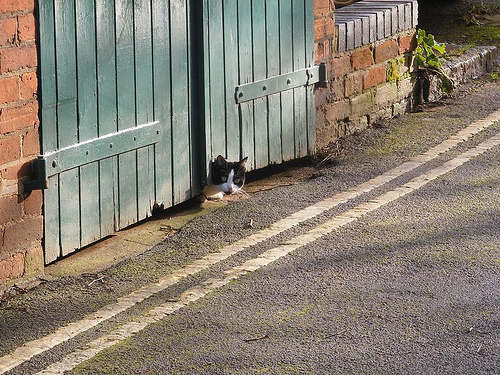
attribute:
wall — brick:
[319, 8, 416, 132]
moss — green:
[366, 47, 416, 100]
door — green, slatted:
[196, 0, 328, 190]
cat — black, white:
[204, 153, 250, 203]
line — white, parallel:
[44, 132, 499, 374]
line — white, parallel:
[0, 101, 499, 370]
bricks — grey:
[334, 20, 355, 49]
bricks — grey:
[335, 17, 361, 48]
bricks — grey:
[332, 16, 369, 46]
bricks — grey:
[338, 7, 391, 37]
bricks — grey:
[355, 1, 412, 30]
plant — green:
[407, 25, 455, 97]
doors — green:
[45, 6, 305, 266]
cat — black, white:
[193, 151, 278, 213]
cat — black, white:
[188, 146, 250, 195]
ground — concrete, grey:
[151, 200, 498, 370]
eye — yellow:
[220, 175, 229, 182]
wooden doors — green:
[36, 0, 319, 254]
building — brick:
[4, 2, 421, 284]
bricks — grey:
[310, 2, 413, 104]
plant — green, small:
[408, 28, 451, 94]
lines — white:
[288, 181, 392, 244]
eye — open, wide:
[219, 173, 230, 182]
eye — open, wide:
[234, 177, 242, 185]